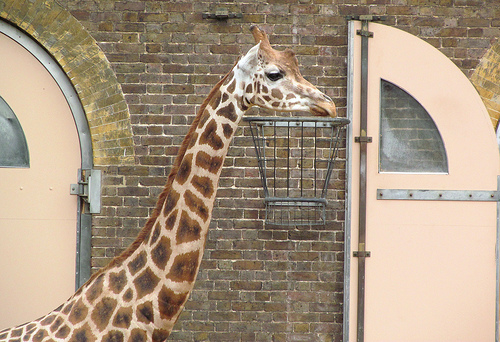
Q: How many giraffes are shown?
A: One.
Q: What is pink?
A: Doors.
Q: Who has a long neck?
A: Giraffe.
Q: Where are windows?
A: On doors.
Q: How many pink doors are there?
A: Two.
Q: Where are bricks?
A: On a building.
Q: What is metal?
A: Basket.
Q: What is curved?
A: Doors.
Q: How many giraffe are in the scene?
A: One.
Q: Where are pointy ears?
A: On giraffe's head.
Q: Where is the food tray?
A: In the wall.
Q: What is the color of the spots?
A: Brown.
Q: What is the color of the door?
A: Peach.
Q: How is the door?
A: Open.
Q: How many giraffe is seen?
A: 1.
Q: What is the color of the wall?
A: Red.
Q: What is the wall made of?
A: Bricks.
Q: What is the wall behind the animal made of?
A: Brick.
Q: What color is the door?
A: Light pink.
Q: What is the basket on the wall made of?
A: Metal.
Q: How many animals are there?
A: One.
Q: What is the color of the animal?
A: Brown and white.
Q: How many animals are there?
A: 1.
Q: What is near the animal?
A: Wall.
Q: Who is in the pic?
A: No one.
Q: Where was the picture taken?
A: At the zoo.